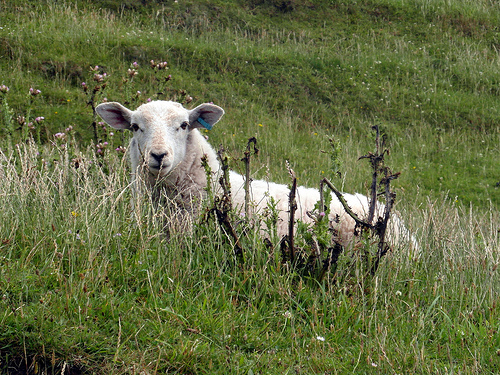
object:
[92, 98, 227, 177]
head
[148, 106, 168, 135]
wool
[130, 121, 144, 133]
eyes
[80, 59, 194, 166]
plant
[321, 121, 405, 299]
plant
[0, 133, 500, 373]
tall weeds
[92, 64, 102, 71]
flowers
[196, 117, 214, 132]
blue tag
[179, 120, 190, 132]
eyes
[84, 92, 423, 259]
sheep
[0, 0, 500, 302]
grass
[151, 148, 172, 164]
sheep nose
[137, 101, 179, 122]
forehead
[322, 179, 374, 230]
twigs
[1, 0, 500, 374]
ground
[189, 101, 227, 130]
ear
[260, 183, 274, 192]
wool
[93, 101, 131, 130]
ear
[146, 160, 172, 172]
mouth